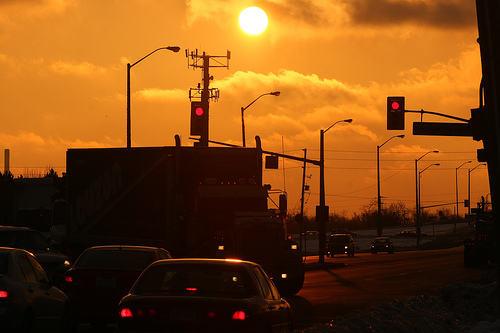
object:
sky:
[0, 0, 498, 221]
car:
[111, 258, 290, 333]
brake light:
[117, 309, 132, 319]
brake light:
[230, 310, 246, 322]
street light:
[373, 134, 405, 238]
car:
[368, 237, 397, 255]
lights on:
[383, 243, 389, 247]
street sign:
[410, 121, 479, 136]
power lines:
[301, 156, 479, 162]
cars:
[64, 246, 179, 317]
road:
[271, 248, 467, 333]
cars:
[326, 233, 356, 256]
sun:
[237, 5, 270, 39]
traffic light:
[190, 100, 212, 138]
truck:
[64, 145, 306, 298]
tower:
[183, 46, 235, 148]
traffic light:
[385, 94, 406, 129]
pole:
[404, 102, 470, 122]